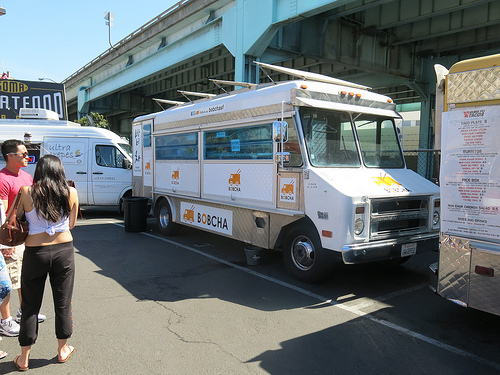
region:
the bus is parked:
[119, 87, 439, 282]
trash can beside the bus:
[115, 192, 155, 237]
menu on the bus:
[436, 105, 498, 251]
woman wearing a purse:
[0, 154, 75, 366]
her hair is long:
[32, 152, 72, 227]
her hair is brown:
[25, 151, 72, 221]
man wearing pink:
[0, 138, 39, 236]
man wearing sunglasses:
[3, 152, 30, 165]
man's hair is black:
[0, 137, 30, 169]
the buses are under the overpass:
[22, 4, 498, 176]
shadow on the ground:
[113, 246, 243, 303]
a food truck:
[150, 102, 430, 244]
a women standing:
[23, 159, 81, 369]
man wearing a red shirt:
[1, 172, 22, 195]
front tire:
[288, 232, 321, 276]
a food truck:
[439, 80, 499, 310]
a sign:
[1, 75, 64, 107]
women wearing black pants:
[24, 243, 74, 338]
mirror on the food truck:
[272, 122, 287, 142]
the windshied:
[308, 113, 408, 169]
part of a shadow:
[421, 331, 433, 339]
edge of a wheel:
[286, 252, 308, 270]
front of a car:
[342, 190, 362, 241]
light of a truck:
[355, 215, 361, 241]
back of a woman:
[61, 306, 75, 316]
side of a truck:
[203, 161, 224, 208]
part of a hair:
[36, 191, 43, 205]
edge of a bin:
[127, 193, 136, 208]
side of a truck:
[369, 216, 380, 233]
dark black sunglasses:
[12, 150, 36, 158]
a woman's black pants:
[19, 246, 80, 343]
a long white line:
[119, 226, 493, 373]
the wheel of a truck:
[282, 226, 324, 276]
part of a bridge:
[42, 1, 498, 97]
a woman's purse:
[0, 188, 27, 244]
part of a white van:
[2, 107, 135, 206]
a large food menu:
[435, 102, 498, 236]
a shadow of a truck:
[67, 218, 321, 312]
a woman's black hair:
[31, 154, 71, 226]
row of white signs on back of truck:
[439, 112, 498, 240]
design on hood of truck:
[364, 169, 406, 187]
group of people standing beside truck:
[0, 132, 101, 374]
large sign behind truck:
[0, 79, 67, 114]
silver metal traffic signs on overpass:
[99, 8, 121, 48]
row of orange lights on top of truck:
[298, 85, 400, 105]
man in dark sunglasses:
[3, 145, 33, 168]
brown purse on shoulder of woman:
[0, 186, 34, 246]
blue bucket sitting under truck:
[224, 231, 271, 271]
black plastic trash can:
[107, 185, 161, 248]